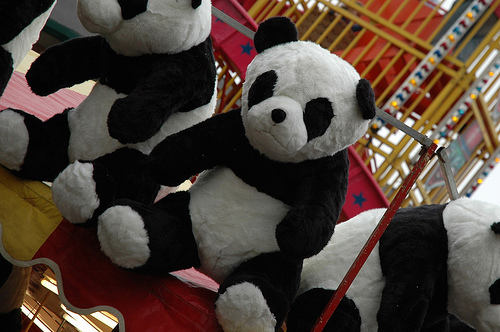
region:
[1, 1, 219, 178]
stuffed panda to the left of stuffed panda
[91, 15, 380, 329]
stuffed panda to the right of stuffed panda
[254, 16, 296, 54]
black ears on panda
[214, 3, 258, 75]
red railing behind panda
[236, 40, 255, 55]
blue star on railing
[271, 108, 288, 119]
black panda nose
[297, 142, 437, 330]
red metal post next to panda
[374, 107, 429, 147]
gray metal railing next to panda ear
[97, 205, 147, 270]
foot is white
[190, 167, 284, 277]
panda belly is white and soft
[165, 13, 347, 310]
black and white stuffed panda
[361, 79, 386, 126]
ear of stuffed panda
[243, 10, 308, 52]
ear of stuffed panda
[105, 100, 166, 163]
paw of the panda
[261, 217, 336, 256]
paw of the panda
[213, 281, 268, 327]
paw of the panda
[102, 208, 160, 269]
paw of the panda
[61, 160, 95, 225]
paw of the panda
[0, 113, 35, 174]
paw of the panda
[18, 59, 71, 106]
paw of the panda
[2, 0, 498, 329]
panda bears hanging at a carnival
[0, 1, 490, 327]
black and white panda bear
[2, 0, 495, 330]
black and white stuff animals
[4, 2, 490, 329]
black and white bears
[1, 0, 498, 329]
black and white stuffed panda bears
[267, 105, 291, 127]
black panda bear nose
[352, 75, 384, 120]
black panda bear nose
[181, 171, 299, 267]
white panda bear stomach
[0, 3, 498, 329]
stuffed animals on a rack hanging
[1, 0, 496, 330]
fluffy panda bears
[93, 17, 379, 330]
One of three Panda bear sitting on table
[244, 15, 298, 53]
ear of panda bear sitting in middle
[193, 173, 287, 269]
belly of big panda bear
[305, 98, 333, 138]
eye of big panda bear in the middle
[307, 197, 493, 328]
panda bear on right side of middle panda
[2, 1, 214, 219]
panda bear left side of middle bear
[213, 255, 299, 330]
bottom leg of middle panda bear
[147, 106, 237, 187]
arm of middle panda bear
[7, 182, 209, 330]
red table panda is on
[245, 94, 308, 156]
nose and mouth of middle panda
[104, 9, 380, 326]
This is ted bear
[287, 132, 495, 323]
This is ted bear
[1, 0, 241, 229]
This is ted bear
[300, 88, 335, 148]
Eye of a ted bear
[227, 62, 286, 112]
Eye of a ted bear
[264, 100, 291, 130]
Nose of a ted bear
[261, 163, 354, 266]
Hand of a ted bear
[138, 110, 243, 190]
Hand of a ted bear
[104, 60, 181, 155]
Hand of a ted bear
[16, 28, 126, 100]
Hand of a ted bear